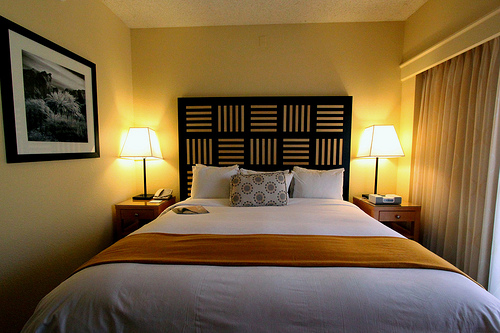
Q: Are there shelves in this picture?
A: No, there are no shelves.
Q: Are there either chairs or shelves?
A: No, there are no shelves or chairs.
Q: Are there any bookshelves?
A: No, there are no bookshelves.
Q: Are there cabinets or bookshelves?
A: No, there are no bookshelves or cabinets.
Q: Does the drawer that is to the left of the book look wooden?
A: Yes, the drawer is wooden.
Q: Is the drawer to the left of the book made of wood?
A: Yes, the drawer is made of wood.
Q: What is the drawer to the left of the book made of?
A: The drawer is made of wood.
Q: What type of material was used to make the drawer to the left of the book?
A: The drawer is made of wood.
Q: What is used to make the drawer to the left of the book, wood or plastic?
A: The drawer is made of wood.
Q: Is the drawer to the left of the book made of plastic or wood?
A: The drawer is made of wood.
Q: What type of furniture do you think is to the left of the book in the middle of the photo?
A: The piece of furniture is a drawer.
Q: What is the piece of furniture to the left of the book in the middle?
A: The piece of furniture is a drawer.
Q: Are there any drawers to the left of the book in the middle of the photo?
A: Yes, there is a drawer to the left of the book.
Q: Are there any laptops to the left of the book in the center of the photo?
A: No, there is a drawer to the left of the book.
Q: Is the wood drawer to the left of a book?
A: Yes, the drawer is to the left of a book.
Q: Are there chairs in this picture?
A: No, there are no chairs.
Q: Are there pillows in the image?
A: Yes, there is a pillow.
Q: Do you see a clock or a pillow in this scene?
A: Yes, there is a pillow.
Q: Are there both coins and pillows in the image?
A: No, there is a pillow but no coins.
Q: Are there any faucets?
A: No, there are no faucets.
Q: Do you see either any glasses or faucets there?
A: No, there are no faucets or glasses.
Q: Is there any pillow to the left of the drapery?
A: Yes, there is a pillow to the left of the drapery.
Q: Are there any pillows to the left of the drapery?
A: Yes, there is a pillow to the left of the drapery.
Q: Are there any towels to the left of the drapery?
A: No, there is a pillow to the left of the drapery.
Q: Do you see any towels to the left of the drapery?
A: No, there is a pillow to the left of the drapery.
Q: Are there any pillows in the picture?
A: Yes, there is a pillow.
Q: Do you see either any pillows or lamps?
A: Yes, there is a pillow.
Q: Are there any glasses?
A: No, there are no glasses.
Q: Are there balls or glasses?
A: No, there are no glasses or balls.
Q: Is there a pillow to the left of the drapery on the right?
A: Yes, there is a pillow to the left of the drape.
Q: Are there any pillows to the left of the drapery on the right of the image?
A: Yes, there is a pillow to the left of the drape.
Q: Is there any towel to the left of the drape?
A: No, there is a pillow to the left of the drape.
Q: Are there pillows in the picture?
A: Yes, there is a pillow.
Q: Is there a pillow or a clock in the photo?
A: Yes, there is a pillow.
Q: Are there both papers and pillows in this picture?
A: No, there is a pillow but no papers.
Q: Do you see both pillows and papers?
A: No, there is a pillow but no papers.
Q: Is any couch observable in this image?
A: No, there are no couches.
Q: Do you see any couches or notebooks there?
A: No, there are no couches or notebooks.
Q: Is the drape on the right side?
A: Yes, the drape is on the right of the image.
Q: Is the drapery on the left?
A: No, the drapery is on the right of the image.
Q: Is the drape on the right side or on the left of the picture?
A: The drape is on the right of the image.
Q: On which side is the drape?
A: The drape is on the right of the image.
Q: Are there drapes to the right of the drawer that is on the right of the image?
A: Yes, there is a drape to the right of the drawer.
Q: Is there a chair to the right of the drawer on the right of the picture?
A: No, there is a drape to the right of the drawer.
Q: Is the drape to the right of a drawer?
A: Yes, the drape is to the right of a drawer.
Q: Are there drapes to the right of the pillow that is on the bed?
A: Yes, there is a drape to the right of the pillow.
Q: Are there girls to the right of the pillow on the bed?
A: No, there is a drape to the right of the pillow.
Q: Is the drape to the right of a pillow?
A: Yes, the drape is to the right of a pillow.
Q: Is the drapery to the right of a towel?
A: No, the drapery is to the right of a pillow.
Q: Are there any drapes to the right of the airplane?
A: Yes, there is a drape to the right of the airplane.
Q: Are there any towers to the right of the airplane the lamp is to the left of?
A: No, there is a drape to the right of the plane.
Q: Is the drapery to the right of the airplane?
A: Yes, the drapery is to the right of the airplane.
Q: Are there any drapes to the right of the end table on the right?
A: Yes, there is a drape to the right of the end table.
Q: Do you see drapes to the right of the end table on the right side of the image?
A: Yes, there is a drape to the right of the end table.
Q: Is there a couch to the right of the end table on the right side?
A: No, there is a drape to the right of the end table.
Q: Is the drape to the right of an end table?
A: Yes, the drape is to the right of an end table.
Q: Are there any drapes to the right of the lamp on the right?
A: Yes, there is a drape to the right of the lamp.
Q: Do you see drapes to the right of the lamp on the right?
A: Yes, there is a drape to the right of the lamp.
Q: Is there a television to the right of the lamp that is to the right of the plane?
A: No, there is a drape to the right of the lamp.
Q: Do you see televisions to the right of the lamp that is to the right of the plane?
A: No, there is a drape to the right of the lamp.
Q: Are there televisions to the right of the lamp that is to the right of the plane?
A: No, there is a drape to the right of the lamp.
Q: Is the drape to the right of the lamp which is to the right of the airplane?
A: Yes, the drape is to the right of the lamp.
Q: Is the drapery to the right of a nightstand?
A: No, the drapery is to the right of the lamp.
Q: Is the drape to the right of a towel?
A: No, the drape is to the right of a pillow.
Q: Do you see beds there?
A: Yes, there is a bed.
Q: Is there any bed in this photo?
A: Yes, there is a bed.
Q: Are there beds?
A: Yes, there is a bed.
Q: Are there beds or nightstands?
A: Yes, there is a bed.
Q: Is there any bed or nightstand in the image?
A: Yes, there is a bed.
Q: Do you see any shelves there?
A: No, there are no shelves.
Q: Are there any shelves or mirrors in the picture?
A: No, there are no shelves or mirrors.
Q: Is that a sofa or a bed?
A: That is a bed.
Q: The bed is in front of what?
A: The bed is in front of the wall.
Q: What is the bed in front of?
A: The bed is in front of the wall.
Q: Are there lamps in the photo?
A: Yes, there is a lamp.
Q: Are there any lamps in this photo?
A: Yes, there is a lamp.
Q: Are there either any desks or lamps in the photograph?
A: Yes, there is a lamp.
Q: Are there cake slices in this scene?
A: No, there are no cake slices.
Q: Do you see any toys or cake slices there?
A: No, there are no cake slices or toys.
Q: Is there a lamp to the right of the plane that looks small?
A: Yes, there is a lamp to the right of the airplane.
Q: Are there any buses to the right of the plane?
A: No, there is a lamp to the right of the plane.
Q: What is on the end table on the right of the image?
A: The lamp is on the end table.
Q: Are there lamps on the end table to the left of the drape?
A: Yes, there is a lamp on the end table.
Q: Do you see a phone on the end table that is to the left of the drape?
A: No, there is a lamp on the end table.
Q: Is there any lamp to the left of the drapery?
A: Yes, there is a lamp to the left of the drapery.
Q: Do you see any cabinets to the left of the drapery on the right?
A: No, there is a lamp to the left of the drape.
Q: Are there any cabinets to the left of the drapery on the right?
A: No, there is a lamp to the left of the drape.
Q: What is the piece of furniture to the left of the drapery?
A: The piece of furniture is an end table.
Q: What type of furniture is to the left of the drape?
A: The piece of furniture is an end table.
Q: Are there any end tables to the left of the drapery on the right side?
A: Yes, there is an end table to the left of the drapery.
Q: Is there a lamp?
A: Yes, there is a lamp.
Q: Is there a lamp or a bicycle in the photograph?
A: Yes, there is a lamp.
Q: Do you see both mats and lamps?
A: No, there is a lamp but no mats.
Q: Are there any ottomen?
A: No, there are no ottomen.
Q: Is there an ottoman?
A: No, there are no ottomen.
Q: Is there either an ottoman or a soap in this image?
A: No, there are no ottomen or soaps.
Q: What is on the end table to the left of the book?
A: The lamp is on the end table.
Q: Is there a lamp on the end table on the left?
A: Yes, there is a lamp on the end table.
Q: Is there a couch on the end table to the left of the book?
A: No, there is a lamp on the end table.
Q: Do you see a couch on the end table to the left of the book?
A: No, there is a lamp on the end table.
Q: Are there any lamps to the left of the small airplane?
A: Yes, there is a lamp to the left of the airplane.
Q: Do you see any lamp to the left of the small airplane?
A: Yes, there is a lamp to the left of the airplane.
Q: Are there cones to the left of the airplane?
A: No, there is a lamp to the left of the airplane.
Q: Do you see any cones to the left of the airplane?
A: No, there is a lamp to the left of the airplane.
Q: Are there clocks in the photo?
A: No, there are no clocks.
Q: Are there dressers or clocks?
A: No, there are no clocks or dressers.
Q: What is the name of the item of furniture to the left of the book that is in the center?
A: The piece of furniture is an end table.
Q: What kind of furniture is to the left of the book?
A: The piece of furniture is an end table.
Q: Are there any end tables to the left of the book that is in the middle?
A: Yes, there is an end table to the left of the book.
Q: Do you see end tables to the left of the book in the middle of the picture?
A: Yes, there is an end table to the left of the book.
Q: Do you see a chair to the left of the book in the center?
A: No, there is an end table to the left of the book.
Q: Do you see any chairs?
A: No, there are no chairs.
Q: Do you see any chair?
A: No, there are no chairs.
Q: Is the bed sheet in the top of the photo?
A: No, the bed sheet is in the bottom of the image.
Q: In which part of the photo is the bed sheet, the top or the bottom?
A: The bed sheet is in the bottom of the image.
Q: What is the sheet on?
A: The sheet is on the bed.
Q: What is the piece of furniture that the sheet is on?
A: The piece of furniture is a bed.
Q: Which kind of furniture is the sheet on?
A: The sheet is on the bed.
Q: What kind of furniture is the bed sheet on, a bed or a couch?
A: The bed sheet is on a bed.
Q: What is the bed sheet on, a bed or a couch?
A: The bed sheet is on a bed.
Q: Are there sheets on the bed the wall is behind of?
A: Yes, there is a sheet on the bed.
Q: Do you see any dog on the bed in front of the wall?
A: No, there is a sheet on the bed.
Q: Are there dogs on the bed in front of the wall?
A: No, there is a sheet on the bed.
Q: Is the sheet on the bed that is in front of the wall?
A: Yes, the sheet is on the bed.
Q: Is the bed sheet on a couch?
A: No, the bed sheet is on the bed.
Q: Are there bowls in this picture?
A: No, there are no bowls.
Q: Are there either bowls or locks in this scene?
A: No, there are no bowls or locks.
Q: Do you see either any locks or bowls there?
A: No, there are no bowls or locks.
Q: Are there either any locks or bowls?
A: No, there are no bowls or locks.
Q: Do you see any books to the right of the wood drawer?
A: Yes, there is a book to the right of the drawer.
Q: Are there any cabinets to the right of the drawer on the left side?
A: No, there is a book to the right of the drawer.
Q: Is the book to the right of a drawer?
A: Yes, the book is to the right of a drawer.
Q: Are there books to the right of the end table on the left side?
A: Yes, there is a book to the right of the end table.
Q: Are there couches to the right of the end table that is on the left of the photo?
A: No, there is a book to the right of the end table.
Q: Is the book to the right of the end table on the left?
A: Yes, the book is to the right of the end table.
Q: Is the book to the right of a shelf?
A: No, the book is to the right of the end table.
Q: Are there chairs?
A: No, there are no chairs.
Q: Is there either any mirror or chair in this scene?
A: No, there are no chairs or mirrors.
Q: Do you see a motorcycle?
A: No, there are no motorcycles.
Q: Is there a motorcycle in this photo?
A: No, there are no motorcycles.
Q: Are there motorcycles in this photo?
A: No, there are no motorcycles.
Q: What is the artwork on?
A: The artwork is on the wall.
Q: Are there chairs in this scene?
A: No, there are no chairs.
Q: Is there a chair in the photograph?
A: No, there are no chairs.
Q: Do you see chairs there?
A: No, there are no chairs.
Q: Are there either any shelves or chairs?
A: No, there are no chairs or shelves.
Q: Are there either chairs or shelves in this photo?
A: No, there are no chairs or shelves.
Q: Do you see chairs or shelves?
A: No, there are no chairs or shelves.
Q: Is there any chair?
A: No, there are no chairs.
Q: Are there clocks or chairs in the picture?
A: No, there are no chairs or clocks.